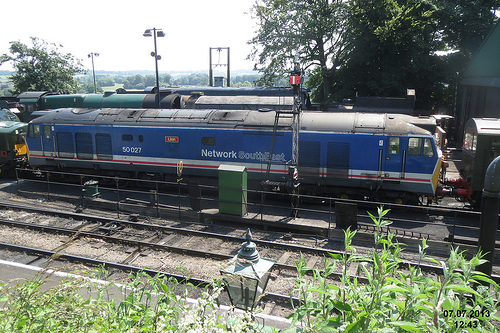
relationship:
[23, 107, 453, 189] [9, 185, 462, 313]
train on tracks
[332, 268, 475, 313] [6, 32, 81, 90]
leaves on tree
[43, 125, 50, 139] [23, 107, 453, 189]
window of train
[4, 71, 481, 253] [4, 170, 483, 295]
train of tracks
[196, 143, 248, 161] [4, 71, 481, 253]
name of train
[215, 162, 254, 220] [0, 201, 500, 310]
box of rails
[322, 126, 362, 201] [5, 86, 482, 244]
door of train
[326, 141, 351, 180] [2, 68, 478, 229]
door on train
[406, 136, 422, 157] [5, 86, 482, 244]
window on train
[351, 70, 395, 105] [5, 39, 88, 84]
trunk on tree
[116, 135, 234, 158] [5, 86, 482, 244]
writing on train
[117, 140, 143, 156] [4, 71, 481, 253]
numbers on train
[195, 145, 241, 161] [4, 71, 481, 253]
letters on train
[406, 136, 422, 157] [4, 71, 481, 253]
window on train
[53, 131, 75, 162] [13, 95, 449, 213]
window on train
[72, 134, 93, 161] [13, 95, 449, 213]
window on train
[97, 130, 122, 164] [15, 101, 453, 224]
window on train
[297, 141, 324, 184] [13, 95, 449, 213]
window on train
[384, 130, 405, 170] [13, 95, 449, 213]
window on train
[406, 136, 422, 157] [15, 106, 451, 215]
window on train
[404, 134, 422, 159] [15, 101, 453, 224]
window on train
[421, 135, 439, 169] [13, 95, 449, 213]
window on train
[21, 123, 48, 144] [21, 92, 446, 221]
window on train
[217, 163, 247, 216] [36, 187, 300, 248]
box on tracks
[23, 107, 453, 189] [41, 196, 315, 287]
train on tracks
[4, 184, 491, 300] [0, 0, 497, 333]
rails at a station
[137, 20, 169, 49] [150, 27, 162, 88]
light on a pole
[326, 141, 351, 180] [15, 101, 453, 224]
door of a train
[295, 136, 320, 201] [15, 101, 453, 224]
door of a train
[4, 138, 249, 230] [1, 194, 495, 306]
fence next to a rail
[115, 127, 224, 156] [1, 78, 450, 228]
windows on side of train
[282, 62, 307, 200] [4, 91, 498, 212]
pole on front of a train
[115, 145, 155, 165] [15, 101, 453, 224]
50027 on train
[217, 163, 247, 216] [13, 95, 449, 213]
box near train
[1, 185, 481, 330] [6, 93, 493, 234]
rail near train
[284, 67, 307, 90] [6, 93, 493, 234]
light above train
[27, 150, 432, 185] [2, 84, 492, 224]
line on side of train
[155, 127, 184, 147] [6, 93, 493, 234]
sign on side of a train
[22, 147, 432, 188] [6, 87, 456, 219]
line on train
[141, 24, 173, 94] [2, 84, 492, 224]
lamp post behind train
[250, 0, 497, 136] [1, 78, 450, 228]
tree behind train